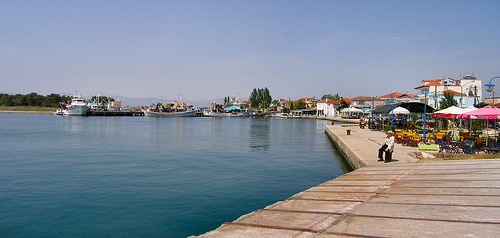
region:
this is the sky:
[137, 4, 367, 87]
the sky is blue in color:
[268, 18, 398, 56]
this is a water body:
[5, 131, 120, 202]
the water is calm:
[79, 132, 184, 196]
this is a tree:
[246, 82, 275, 102]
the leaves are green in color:
[258, 87, 269, 104]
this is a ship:
[58, 103, 93, 119]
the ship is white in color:
[62, 107, 86, 114]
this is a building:
[418, 76, 473, 100]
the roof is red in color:
[425, 71, 441, 86]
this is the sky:
[17, 9, 148, 54]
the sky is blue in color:
[12, 7, 79, 36]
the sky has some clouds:
[8, 47, 213, 89]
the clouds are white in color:
[11, 53, 187, 86]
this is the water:
[23, 122, 190, 226]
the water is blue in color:
[21, 133, 214, 220]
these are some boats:
[51, 95, 245, 117]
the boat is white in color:
[71, 105, 82, 117]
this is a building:
[421, 76, 483, 94]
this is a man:
[377, 125, 397, 160]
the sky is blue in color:
[160, 25, 325, 65]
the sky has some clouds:
[128, 50, 244, 102]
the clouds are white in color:
[11, 51, 83, 90]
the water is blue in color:
[61, 118, 163, 183]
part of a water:
[177, 137, 217, 183]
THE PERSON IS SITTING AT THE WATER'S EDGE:
[371, 128, 398, 173]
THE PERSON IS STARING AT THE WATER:
[372, 124, 410, 184]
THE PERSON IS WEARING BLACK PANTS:
[366, 126, 401, 176]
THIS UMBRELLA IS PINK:
[458, 105, 499, 128]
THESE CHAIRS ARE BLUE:
[432, 131, 487, 158]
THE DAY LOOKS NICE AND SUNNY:
[4, 3, 497, 236]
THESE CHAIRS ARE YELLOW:
[386, 121, 458, 148]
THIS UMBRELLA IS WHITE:
[383, 96, 410, 123]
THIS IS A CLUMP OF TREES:
[238, 82, 284, 127]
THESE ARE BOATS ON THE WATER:
[53, 88, 253, 121]